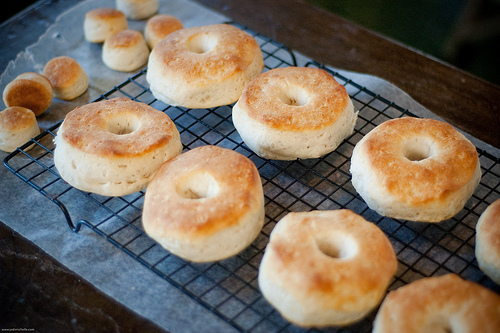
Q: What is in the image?
A: Donuts.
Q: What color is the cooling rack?
A: Black.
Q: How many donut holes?
A: 7.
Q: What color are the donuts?
A: Brown.